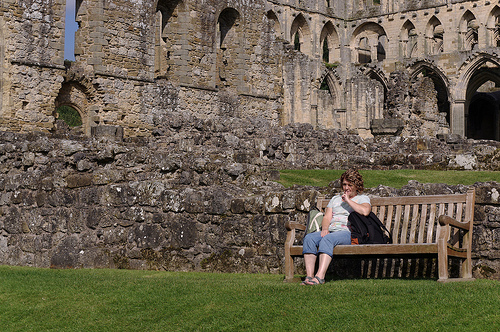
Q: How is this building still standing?
A: It was built to last.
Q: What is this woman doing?
A: Smoking on the wooden bench.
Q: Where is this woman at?
A: The ruins of a building.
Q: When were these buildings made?
A: During the Roman Empire.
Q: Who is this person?
A: A visitor.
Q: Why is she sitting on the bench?
A: To have a view of the ruins.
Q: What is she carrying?
A: A backpack.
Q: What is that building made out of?
A: Pure stone.